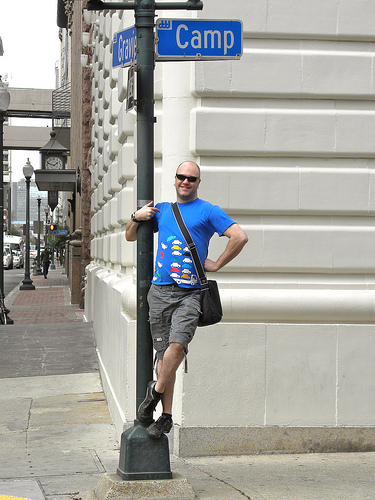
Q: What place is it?
A: It is a sidewalk.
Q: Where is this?
A: This is at the sidewalk.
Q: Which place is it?
A: It is a sidewalk.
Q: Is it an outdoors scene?
A: Yes, it is outdoors.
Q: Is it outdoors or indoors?
A: It is outdoors.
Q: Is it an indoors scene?
A: No, it is outdoors.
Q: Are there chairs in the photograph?
A: No, there are no chairs.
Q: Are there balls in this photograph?
A: No, there are no balls.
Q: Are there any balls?
A: No, there are no balls.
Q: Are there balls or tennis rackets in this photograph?
A: No, there are no balls or tennis rackets.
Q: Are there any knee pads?
A: No, there are no knee pads.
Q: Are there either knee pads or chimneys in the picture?
A: No, there are no knee pads or chimneys.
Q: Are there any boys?
A: No, there are no boys.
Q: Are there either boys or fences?
A: No, there are no boys or fences.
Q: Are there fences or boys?
A: No, there are no boys or fences.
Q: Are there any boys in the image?
A: No, there are no boys.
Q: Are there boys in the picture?
A: No, there are no boys.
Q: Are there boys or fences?
A: No, there are no boys or fences.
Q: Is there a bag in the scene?
A: Yes, there is a bag.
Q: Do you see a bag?
A: Yes, there is a bag.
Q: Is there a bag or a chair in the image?
A: Yes, there is a bag.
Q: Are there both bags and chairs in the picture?
A: No, there is a bag but no chairs.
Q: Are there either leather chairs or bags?
A: Yes, there is a leather bag.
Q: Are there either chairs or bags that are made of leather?
A: Yes, the bag is made of leather.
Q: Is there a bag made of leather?
A: Yes, there is a bag that is made of leather.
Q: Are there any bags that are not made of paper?
A: Yes, there is a bag that is made of leather.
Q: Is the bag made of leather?
A: Yes, the bag is made of leather.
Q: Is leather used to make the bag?
A: Yes, the bag is made of leather.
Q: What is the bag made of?
A: The bag is made of leather.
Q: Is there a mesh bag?
A: No, there is a bag but it is made of leather.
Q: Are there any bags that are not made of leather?
A: No, there is a bag but it is made of leather.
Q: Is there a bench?
A: No, there are no benches.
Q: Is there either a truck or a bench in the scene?
A: No, there are no benches or trucks.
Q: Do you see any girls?
A: No, there are no girls.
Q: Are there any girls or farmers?
A: No, there are no girls or farmers.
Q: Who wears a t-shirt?
A: The man wears a t-shirt.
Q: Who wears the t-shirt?
A: The man wears a t-shirt.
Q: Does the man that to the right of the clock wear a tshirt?
A: Yes, the man wears a tshirt.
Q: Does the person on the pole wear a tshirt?
A: Yes, the man wears a tshirt.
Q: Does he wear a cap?
A: No, the man wears a tshirt.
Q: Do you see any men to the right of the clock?
A: Yes, there is a man to the right of the clock.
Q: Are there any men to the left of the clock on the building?
A: No, the man is to the right of the clock.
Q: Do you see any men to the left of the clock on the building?
A: No, the man is to the right of the clock.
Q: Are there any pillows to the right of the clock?
A: No, there is a man to the right of the clock.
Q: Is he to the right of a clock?
A: Yes, the man is to the right of a clock.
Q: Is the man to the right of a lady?
A: No, the man is to the right of a clock.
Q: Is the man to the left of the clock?
A: No, the man is to the right of the clock.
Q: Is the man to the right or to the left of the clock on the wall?
A: The man is to the right of the clock.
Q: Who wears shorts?
A: The man wears shorts.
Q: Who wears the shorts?
A: The man wears shorts.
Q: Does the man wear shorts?
A: Yes, the man wears shorts.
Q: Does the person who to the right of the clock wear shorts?
A: Yes, the man wears shorts.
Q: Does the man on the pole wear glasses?
A: No, the man wears shorts.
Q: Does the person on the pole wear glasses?
A: No, the man wears shorts.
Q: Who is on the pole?
A: The man is on the pole.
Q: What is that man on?
A: The man is on the pole.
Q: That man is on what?
A: The man is on the pole.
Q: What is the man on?
A: The man is on the pole.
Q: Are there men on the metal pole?
A: Yes, there is a man on the pole.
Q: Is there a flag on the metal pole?
A: No, there is a man on the pole.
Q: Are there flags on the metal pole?
A: No, there is a man on the pole.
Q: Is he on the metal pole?
A: Yes, the man is on the pole.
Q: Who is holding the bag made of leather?
A: The man is holding the bag.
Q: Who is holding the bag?
A: The man is holding the bag.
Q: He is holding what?
A: The man is holding the bag.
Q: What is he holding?
A: The man is holding the bag.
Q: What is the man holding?
A: The man is holding the bag.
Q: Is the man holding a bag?
A: Yes, the man is holding a bag.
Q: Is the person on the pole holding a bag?
A: Yes, the man is holding a bag.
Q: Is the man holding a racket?
A: No, the man is holding a bag.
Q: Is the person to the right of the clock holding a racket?
A: No, the man is holding a bag.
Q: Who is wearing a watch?
A: The man is wearing a watch.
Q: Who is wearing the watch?
A: The man is wearing a watch.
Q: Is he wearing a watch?
A: Yes, the man is wearing a watch.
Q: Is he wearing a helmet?
A: No, the man is wearing a watch.